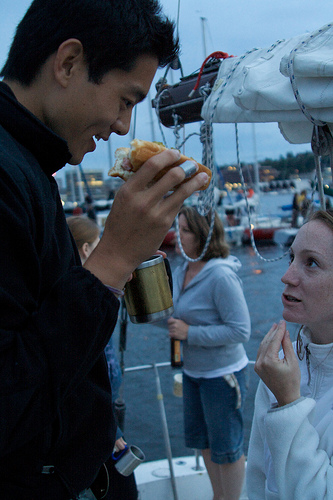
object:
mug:
[97, 435, 172, 488]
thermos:
[109, 247, 181, 322]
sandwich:
[107, 138, 214, 190]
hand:
[101, 148, 212, 261]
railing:
[124, 361, 191, 473]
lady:
[163, 202, 259, 450]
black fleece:
[0, 80, 118, 495]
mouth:
[279, 290, 306, 306]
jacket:
[0, 80, 123, 499]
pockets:
[47, 374, 118, 488]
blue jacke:
[166, 256, 248, 373]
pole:
[183, 15, 241, 176]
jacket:
[164, 264, 252, 385]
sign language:
[253, 290, 305, 409]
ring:
[178, 153, 199, 180]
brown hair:
[176, 202, 228, 263]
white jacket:
[248, 337, 329, 489]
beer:
[171, 326, 180, 365]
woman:
[153, 197, 253, 498]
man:
[1, 1, 212, 498]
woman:
[240, 208, 332, 500]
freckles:
[302, 271, 331, 297]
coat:
[165, 251, 254, 380]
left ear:
[53, 37, 82, 87]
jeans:
[176, 352, 254, 469]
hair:
[1, 0, 181, 88]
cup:
[115, 253, 182, 323]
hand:
[114, 434, 126, 452]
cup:
[111, 443, 145, 477]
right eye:
[301, 252, 320, 271]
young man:
[2, 9, 206, 488]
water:
[224, 248, 288, 345]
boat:
[206, 197, 288, 249]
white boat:
[148, 457, 165, 492]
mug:
[117, 252, 179, 327]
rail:
[122, 361, 185, 498]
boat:
[132, 452, 247, 498]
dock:
[60, 178, 292, 246]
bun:
[106, 137, 214, 192]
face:
[282, 209, 332, 344]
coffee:
[119, 250, 178, 328]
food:
[106, 137, 216, 206]